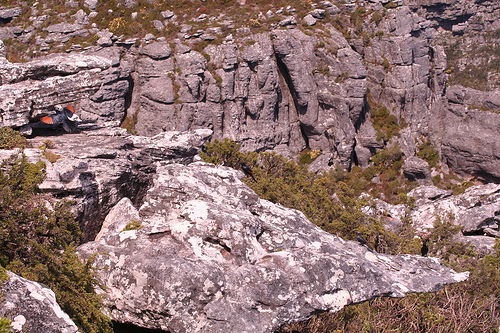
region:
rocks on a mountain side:
[96, 29, 114, 48]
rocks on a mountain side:
[358, 136, 386, 147]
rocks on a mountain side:
[311, 9, 327, 18]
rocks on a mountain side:
[405, 157, 428, 174]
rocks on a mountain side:
[17, 22, 39, 39]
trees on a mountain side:
[9, 157, 86, 293]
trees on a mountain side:
[235, 144, 394, 254]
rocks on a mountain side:
[459, 184, 491, 221]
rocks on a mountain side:
[158, 273, 232, 320]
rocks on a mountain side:
[192, 56, 240, 116]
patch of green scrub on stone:
[4, 119, 41, 163]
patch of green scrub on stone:
[2, 2, 90, 62]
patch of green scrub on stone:
[94, 1, 212, 46]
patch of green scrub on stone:
[218, 2, 338, 43]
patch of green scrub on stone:
[359, 86, 405, 148]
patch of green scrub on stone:
[412, 127, 471, 202]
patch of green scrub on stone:
[114, 106, 146, 148]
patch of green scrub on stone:
[363, 142, 451, 255]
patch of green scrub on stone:
[445, 26, 495, 98]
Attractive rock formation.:
[4, 3, 499, 330]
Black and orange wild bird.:
[26, 98, 86, 135]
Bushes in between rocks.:
[191, 133, 409, 235]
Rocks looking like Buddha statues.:
[178, 30, 293, 130]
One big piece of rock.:
[84, 163, 468, 331]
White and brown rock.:
[100, 165, 455, 315]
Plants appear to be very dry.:
[208, 138, 497, 328]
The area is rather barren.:
[5, 8, 497, 329]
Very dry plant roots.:
[438, 286, 496, 328]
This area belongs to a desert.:
[3, 4, 498, 331]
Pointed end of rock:
[417, 258, 469, 285]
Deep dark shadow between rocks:
[267, 34, 300, 108]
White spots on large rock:
[165, 198, 213, 246]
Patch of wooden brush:
[431, 294, 494, 331]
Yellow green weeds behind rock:
[276, 166, 342, 208]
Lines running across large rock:
[15, 87, 109, 104]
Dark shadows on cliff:
[423, 1, 455, 33]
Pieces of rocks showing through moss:
[154, 7, 236, 36]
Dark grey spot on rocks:
[80, 176, 99, 221]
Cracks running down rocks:
[216, 55, 261, 101]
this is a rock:
[192, 35, 331, 122]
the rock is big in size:
[181, 37, 339, 131]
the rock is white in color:
[101, 188, 281, 319]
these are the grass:
[271, 168, 319, 206]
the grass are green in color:
[281, 170, 316, 195]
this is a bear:
[23, 100, 81, 137]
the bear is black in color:
[30, 108, 76, 141]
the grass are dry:
[163, 4, 211, 24]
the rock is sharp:
[113, 196, 134, 216]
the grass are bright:
[19, 222, 78, 279]